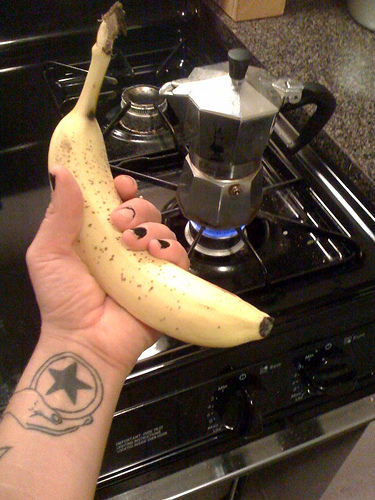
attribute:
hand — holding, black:
[25, 212, 100, 500]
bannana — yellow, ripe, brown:
[59, 114, 253, 325]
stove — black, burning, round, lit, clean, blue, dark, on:
[208, 212, 370, 430]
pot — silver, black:
[176, 62, 287, 194]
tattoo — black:
[6, 349, 103, 454]